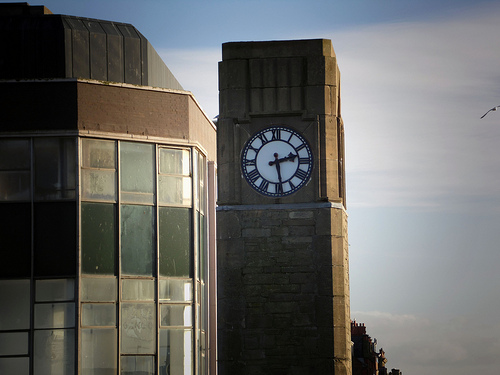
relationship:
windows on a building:
[3, 198, 203, 278] [5, 3, 222, 373]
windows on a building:
[9, 283, 191, 367] [5, 3, 222, 373]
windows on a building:
[4, 135, 195, 197] [5, 3, 222, 373]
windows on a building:
[2, 135, 202, 203] [5, 3, 222, 373]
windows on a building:
[4, 279, 202, 371] [5, 3, 222, 373]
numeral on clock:
[268, 125, 285, 142] [234, 119, 323, 203]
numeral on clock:
[285, 130, 298, 144] [233, 122, 321, 198]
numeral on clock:
[291, 139, 307, 155] [235, 123, 314, 196]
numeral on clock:
[291, 152, 311, 165] [238, 125, 317, 195]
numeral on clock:
[293, 166, 310, 183] [238, 125, 317, 195]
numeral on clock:
[285, 174, 301, 190] [239, 119, 312, 201]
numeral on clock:
[266, 177, 286, 198] [235, 123, 314, 196]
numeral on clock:
[257, 177, 271, 194] [235, 123, 314, 196]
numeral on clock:
[242, 166, 263, 186] [238, 125, 317, 195]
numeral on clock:
[242, 155, 257, 168] [231, 120, 315, 200]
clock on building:
[238, 125, 317, 195] [0, 2, 354, 375]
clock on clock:
[241, 127, 313, 198] [235, 123, 314, 196]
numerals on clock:
[255, 130, 267, 146] [231, 120, 315, 200]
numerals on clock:
[245, 142, 260, 157] [231, 120, 315, 200]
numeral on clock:
[246, 159, 256, 166] [231, 120, 315, 200]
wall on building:
[4, 128, 214, 371] [5, 3, 222, 373]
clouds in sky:
[154, 13, 490, 217] [26, 0, 497, 370]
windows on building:
[193, 283, 211, 373] [5, 3, 222, 373]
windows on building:
[81, 199, 121, 279] [5, 3, 222, 373]